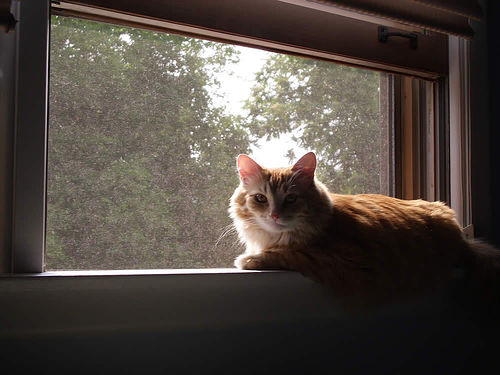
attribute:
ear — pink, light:
[289, 149, 320, 176]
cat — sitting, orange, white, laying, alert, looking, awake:
[219, 150, 498, 299]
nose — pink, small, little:
[267, 210, 283, 222]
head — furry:
[226, 147, 330, 239]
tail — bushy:
[460, 236, 500, 271]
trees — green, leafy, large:
[40, 11, 390, 275]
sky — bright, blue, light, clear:
[60, 26, 365, 192]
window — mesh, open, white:
[9, 2, 464, 291]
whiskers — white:
[213, 213, 270, 248]